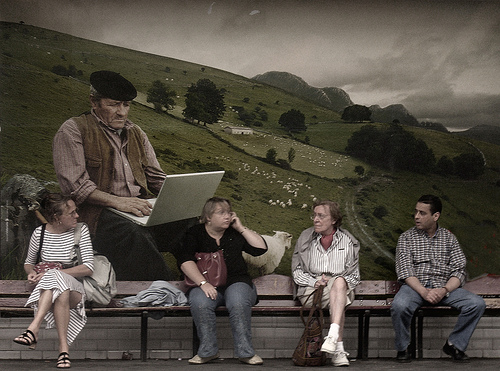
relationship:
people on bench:
[35, 187, 465, 267] [12, 282, 481, 337]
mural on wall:
[3, 16, 498, 273] [15, 9, 481, 297]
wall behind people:
[15, 9, 481, 297] [35, 187, 465, 267]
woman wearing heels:
[27, 193, 114, 363] [13, 326, 75, 368]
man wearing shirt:
[391, 225, 468, 289] [378, 210, 468, 308]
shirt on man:
[395, 221, 498, 330] [391, 225, 468, 289]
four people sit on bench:
[10, 188, 499, 364] [2, 300, 496, 365]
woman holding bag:
[173, 195, 267, 365] [290, 306, 327, 368]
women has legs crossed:
[292, 201, 362, 369] [313, 272, 362, 365]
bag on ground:
[290, 306, 327, 368] [0, 352, 493, 370]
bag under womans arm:
[290, 306, 327, 368] [177, 231, 226, 302]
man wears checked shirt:
[391, 194, 483, 362] [394, 226, 467, 297]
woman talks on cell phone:
[173, 195, 267, 365] [227, 207, 238, 232]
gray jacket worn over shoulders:
[290, 222, 363, 294] [293, 233, 361, 257]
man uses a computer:
[53, 66, 204, 285] [102, 168, 224, 228]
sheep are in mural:
[217, 152, 317, 217] [3, 16, 498, 273]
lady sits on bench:
[12, 193, 102, 366] [2, 300, 496, 365]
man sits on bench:
[391, 225, 468, 289] [2, 300, 496, 365]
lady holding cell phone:
[12, 193, 102, 366] [227, 207, 238, 232]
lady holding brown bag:
[12, 193, 102, 366] [290, 306, 327, 368]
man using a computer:
[391, 225, 468, 289] [102, 168, 224, 228]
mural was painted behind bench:
[3, 16, 498, 273] [2, 300, 496, 365]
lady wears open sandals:
[12, 193, 102, 366] [13, 326, 75, 368]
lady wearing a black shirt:
[12, 193, 102, 366] [173, 224, 265, 293]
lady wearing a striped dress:
[12, 193, 102, 366] [25, 221, 96, 333]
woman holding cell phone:
[173, 195, 267, 365] [227, 207, 238, 232]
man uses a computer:
[391, 225, 468, 289] [102, 168, 224, 228]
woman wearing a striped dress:
[173, 195, 267, 365] [25, 221, 96, 333]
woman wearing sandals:
[173, 195, 267, 365] [13, 326, 75, 368]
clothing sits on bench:
[117, 279, 188, 311] [2, 300, 496, 365]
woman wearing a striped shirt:
[173, 195, 267, 365] [290, 227, 364, 297]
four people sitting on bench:
[10, 188, 499, 364] [2, 300, 496, 365]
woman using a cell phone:
[173, 195, 267, 365] [227, 207, 238, 232]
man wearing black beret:
[391, 225, 468, 289] [86, 68, 139, 103]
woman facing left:
[173, 195, 267, 365] [306, 199, 338, 234]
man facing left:
[391, 225, 468, 289] [414, 195, 442, 232]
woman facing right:
[173, 195, 267, 365] [196, 198, 235, 233]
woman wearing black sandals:
[173, 195, 267, 365] [13, 326, 75, 368]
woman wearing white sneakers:
[173, 195, 267, 365] [321, 333, 353, 368]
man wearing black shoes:
[391, 225, 468, 289] [395, 339, 470, 365]